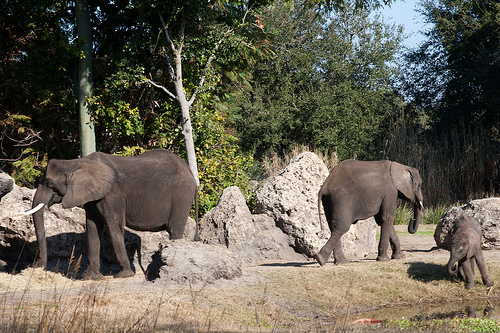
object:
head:
[22, 158, 116, 270]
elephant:
[21, 148, 200, 281]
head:
[390, 161, 424, 235]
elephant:
[312, 158, 423, 266]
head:
[446, 228, 481, 274]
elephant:
[446, 215, 495, 290]